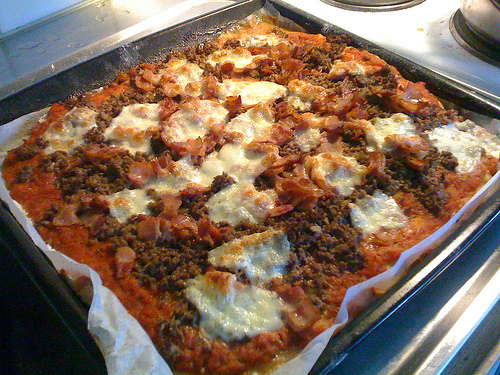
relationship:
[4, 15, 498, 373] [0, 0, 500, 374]
food on dish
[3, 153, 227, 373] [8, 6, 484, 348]
sauce in food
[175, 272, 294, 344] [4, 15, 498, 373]
cheese on top of food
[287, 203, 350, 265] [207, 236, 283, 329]
meat next to cheese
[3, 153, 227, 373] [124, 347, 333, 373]
sauce around edges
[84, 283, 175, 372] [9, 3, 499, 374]
liner paper around dish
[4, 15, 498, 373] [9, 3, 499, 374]
food in dish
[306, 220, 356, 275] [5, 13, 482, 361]
topping in mix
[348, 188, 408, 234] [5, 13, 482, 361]
topping in mix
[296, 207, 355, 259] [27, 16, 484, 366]
topping in pasta mix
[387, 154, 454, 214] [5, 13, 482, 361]
topping in mix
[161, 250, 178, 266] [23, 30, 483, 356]
topping in mix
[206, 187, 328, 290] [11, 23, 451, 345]
topping in mix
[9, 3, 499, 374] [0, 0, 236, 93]
dish rests on top surface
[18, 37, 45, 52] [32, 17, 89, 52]
liquid on surface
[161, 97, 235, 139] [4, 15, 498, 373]
sauce in food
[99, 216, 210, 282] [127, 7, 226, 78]
meat on plate